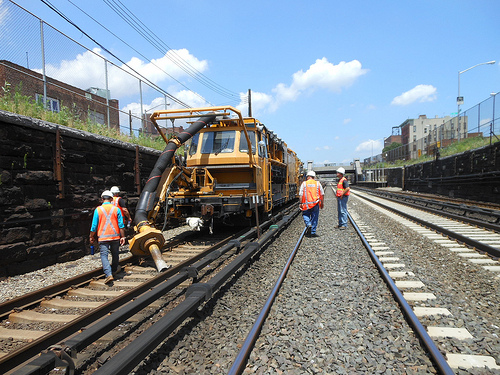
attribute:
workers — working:
[331, 166, 355, 233]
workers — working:
[298, 168, 326, 240]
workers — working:
[105, 185, 136, 248]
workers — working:
[83, 189, 129, 292]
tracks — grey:
[1, 184, 303, 374]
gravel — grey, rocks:
[137, 181, 499, 371]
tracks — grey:
[351, 180, 499, 275]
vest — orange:
[334, 176, 353, 200]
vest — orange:
[300, 179, 324, 211]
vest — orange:
[111, 195, 128, 224]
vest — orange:
[93, 204, 125, 246]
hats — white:
[334, 163, 347, 177]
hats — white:
[304, 169, 317, 179]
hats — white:
[109, 184, 120, 194]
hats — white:
[99, 189, 115, 203]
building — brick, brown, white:
[1, 58, 127, 136]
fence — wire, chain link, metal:
[1, 0, 207, 147]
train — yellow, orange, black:
[160, 124, 312, 234]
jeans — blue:
[335, 192, 350, 227]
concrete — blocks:
[444, 348, 495, 374]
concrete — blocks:
[425, 320, 475, 343]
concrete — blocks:
[413, 302, 452, 322]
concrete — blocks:
[401, 288, 439, 307]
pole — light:
[456, 54, 497, 136]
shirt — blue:
[86, 204, 127, 234]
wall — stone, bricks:
[1, 110, 196, 283]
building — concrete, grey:
[398, 111, 471, 164]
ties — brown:
[7, 304, 85, 326]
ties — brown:
[38, 292, 107, 314]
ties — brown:
[67, 284, 127, 301]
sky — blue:
[1, 1, 498, 170]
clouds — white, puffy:
[388, 82, 438, 115]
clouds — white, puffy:
[235, 49, 371, 136]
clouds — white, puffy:
[29, 44, 211, 92]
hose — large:
[129, 109, 219, 277]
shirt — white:
[299, 177, 325, 203]